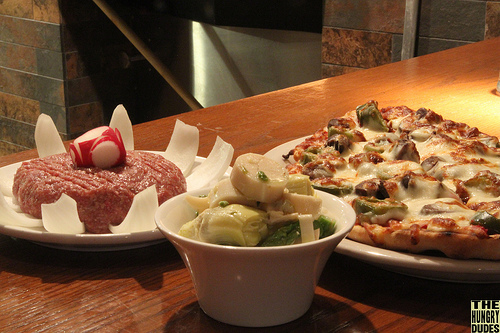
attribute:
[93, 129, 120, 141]
radish — garnish, sliced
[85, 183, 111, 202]
beef — patty, raw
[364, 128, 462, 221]
pizza — vegetable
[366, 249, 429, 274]
plate — ceramic, white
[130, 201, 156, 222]
onion — piece, raw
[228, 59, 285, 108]
table — wood, oak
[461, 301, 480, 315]
watermark — here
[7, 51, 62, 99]
wall — brick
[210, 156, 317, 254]
vegetables — cooked, green